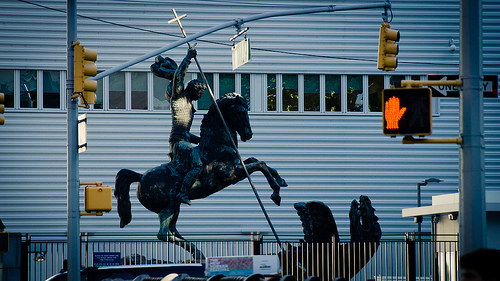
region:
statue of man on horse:
[115, 47, 282, 259]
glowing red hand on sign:
[378, 95, 408, 132]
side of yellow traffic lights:
[71, 45, 98, 99]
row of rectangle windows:
[262, 72, 370, 114]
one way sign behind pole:
[425, 70, 497, 97]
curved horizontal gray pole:
[193, 2, 388, 39]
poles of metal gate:
[271, 239, 408, 276]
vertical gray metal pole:
[456, 1, 485, 238]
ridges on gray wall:
[288, 119, 367, 178]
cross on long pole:
[166, 7, 274, 230]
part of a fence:
[352, 226, 368, 247]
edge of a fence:
[315, 235, 324, 250]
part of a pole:
[468, 189, 475, 204]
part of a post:
[392, 104, 409, 127]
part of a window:
[297, 71, 315, 97]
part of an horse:
[222, 120, 224, 128]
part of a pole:
[76, 148, 86, 172]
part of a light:
[387, 100, 406, 135]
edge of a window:
[334, 93, 355, 110]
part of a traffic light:
[93, 73, 125, 91]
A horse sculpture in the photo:
[115, 45, 285, 247]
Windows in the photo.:
[280, 75, 355, 106]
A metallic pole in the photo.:
[453, 167, 493, 253]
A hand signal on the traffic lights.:
[379, 92, 433, 136]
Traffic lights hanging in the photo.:
[376, 9, 403, 72]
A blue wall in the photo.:
[307, 130, 403, 196]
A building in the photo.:
[291, 39, 381, 203]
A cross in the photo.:
[164, 0, 199, 38]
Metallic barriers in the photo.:
[29, 233, 149, 275]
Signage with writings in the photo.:
[205, 251, 285, 277]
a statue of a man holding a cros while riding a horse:
[108, 17, 320, 273]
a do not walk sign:
[362, 69, 442, 147]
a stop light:
[66, 35, 111, 116]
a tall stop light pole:
[54, 110, 92, 277]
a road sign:
[222, 17, 260, 68]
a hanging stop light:
[352, 12, 411, 77]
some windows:
[272, 68, 366, 112]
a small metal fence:
[332, 232, 420, 271]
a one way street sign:
[420, 64, 495, 103]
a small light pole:
[407, 160, 444, 195]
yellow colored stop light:
[377, 18, 398, 66]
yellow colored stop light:
[71, 40, 103, 100]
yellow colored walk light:
[78, 178, 112, 214]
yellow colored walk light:
[380, 78, 467, 145]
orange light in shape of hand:
[380, 95, 406, 125]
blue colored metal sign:
[92, 250, 118, 270]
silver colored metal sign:
[228, 40, 250, 70]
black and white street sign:
[428, 73, 499, 99]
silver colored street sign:
[72, 115, 87, 146]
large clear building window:
[303, 74, 319, 111]